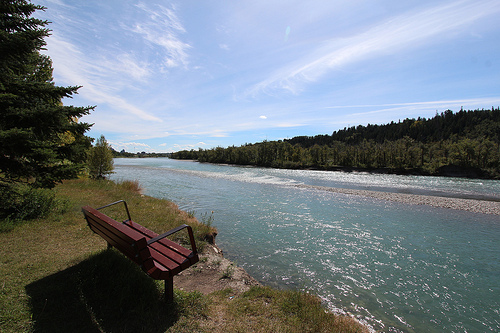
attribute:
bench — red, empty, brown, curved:
[80, 200, 201, 301]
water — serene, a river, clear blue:
[102, 152, 497, 333]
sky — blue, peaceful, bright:
[28, 1, 499, 152]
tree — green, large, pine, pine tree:
[1, 1, 98, 194]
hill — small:
[169, 103, 500, 180]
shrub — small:
[86, 135, 115, 181]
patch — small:
[162, 251, 257, 300]